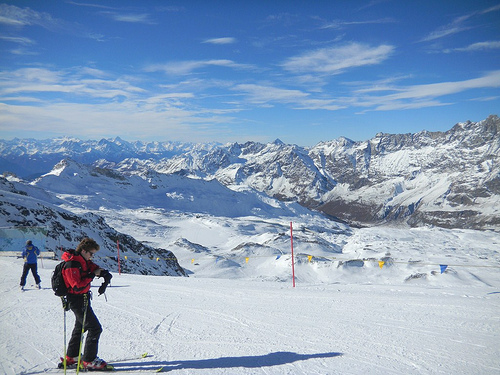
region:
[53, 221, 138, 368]
this is a person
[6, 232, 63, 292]
this is a person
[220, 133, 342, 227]
a mountain covered in snow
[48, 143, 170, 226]
a mountain covered in snow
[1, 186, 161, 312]
a mountain covered in snow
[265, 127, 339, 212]
a mountain covered in snow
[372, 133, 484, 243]
a mountain covered in snow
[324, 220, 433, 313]
a mountain covered in snow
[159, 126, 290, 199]
a mountain covered in snow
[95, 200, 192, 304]
a mountain covered in snow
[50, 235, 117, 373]
Man in red and black jacket preparing to ski.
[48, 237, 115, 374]
Man wearing black back pack.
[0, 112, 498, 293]
Person in blue jacket and black pants skiing.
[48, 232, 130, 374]
Man wearing black shades.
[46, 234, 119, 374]
Man wearing red and white ski shoes.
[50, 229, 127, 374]
Man wearing black gloves on hands.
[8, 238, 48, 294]
Person wearing black ski pants.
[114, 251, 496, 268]
Yellow flags on rope.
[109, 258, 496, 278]
Blue flag on rope.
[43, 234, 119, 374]
Man win yellow ski poles.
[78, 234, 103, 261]
man with short hair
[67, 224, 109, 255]
person wearing goggles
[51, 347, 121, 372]
red ski shoes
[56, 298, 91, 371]
two ski poles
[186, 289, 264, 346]
white snow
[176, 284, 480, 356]
white snow on the ground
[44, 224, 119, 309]
skier wearing a red jacket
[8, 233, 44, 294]
a person skiing wearing a blue jacket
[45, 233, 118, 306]
a person wearing black backpack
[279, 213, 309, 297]
a red pole in the snow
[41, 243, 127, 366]
skier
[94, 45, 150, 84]
white clouds in blue sky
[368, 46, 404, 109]
white clouds in blue sky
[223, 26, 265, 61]
white clouds in blue sky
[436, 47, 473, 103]
white clouds in blue sky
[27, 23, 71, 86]
white clouds in blue sky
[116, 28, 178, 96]
white clouds in blue sky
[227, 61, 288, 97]
white clouds in blue sky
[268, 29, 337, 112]
white clouds in blue sky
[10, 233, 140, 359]
These people are skiing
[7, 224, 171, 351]
The people are on a mountain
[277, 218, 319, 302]
Red pole sticking out of the ground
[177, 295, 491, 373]
The ground is covered in snow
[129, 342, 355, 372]
Skiers shadow in the snow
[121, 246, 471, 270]
Blue and yellow flags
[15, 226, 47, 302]
Person is skiing downhill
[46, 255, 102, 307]
Person is wearing a backpack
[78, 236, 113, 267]
Person is wearing ski goggles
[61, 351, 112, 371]
Person is wearing snow boots